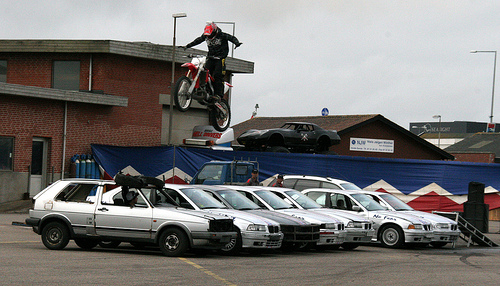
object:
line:
[179, 253, 236, 284]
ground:
[2, 215, 498, 285]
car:
[10, 176, 236, 257]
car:
[88, 183, 284, 253]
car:
[211, 183, 324, 252]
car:
[265, 185, 376, 250]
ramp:
[431, 208, 500, 249]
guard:
[243, 169, 263, 187]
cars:
[299, 188, 428, 248]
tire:
[38, 215, 69, 249]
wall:
[0, 54, 230, 207]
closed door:
[28, 139, 47, 196]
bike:
[174, 51, 233, 133]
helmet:
[203, 22, 216, 36]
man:
[183, 22, 243, 93]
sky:
[265, 10, 475, 120]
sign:
[348, 137, 396, 154]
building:
[229, 114, 454, 162]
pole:
[469, 49, 499, 128]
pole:
[168, 12, 188, 144]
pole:
[59, 102, 69, 180]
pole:
[206, 20, 237, 59]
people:
[247, 170, 285, 188]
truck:
[187, 158, 263, 185]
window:
[51, 59, 81, 91]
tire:
[173, 75, 193, 111]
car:
[187, 185, 321, 253]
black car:
[236, 121, 343, 154]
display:
[236, 148, 498, 165]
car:
[237, 121, 340, 151]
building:
[0, 39, 253, 214]